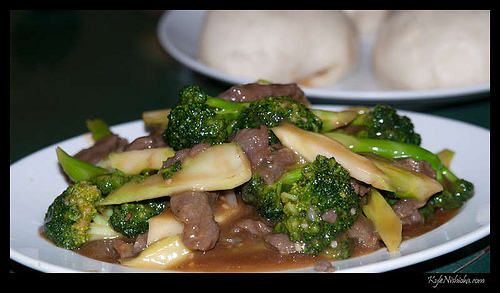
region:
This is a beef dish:
[106, 137, 238, 233]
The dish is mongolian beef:
[147, 104, 347, 260]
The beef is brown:
[130, 190, 270, 256]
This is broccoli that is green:
[230, 120, 387, 290]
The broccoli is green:
[250, 130, 338, 281]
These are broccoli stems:
[92, 160, 194, 187]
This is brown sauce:
[70, 210, 333, 282]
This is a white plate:
[50, 255, 85, 283]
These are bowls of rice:
[230, 16, 381, 97]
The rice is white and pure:
[199, 40, 358, 91]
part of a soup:
[225, 220, 256, 275]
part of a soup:
[253, 218, 280, 247]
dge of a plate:
[427, 209, 453, 256]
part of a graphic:
[445, 264, 482, 286]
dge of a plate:
[418, 238, 442, 264]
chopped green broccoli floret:
[164, 87, 244, 146]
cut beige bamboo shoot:
[90, 139, 252, 205]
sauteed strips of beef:
[170, 189, 222, 253]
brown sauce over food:
[78, 229, 473, 274]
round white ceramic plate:
[6, 103, 493, 273]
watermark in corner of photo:
[422, 269, 488, 290]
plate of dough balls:
[152, 10, 489, 107]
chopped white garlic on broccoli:
[290, 233, 339, 255]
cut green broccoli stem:
[52, 135, 115, 184]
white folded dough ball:
[198, 13, 360, 92]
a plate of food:
[3, 77, 488, 257]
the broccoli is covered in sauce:
[158, 56, 402, 225]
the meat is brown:
[182, 60, 317, 190]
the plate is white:
[0, 79, 472, 260]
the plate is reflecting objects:
[412, 189, 488, 254]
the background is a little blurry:
[37, 0, 480, 110]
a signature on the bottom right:
[419, 269, 497, 289]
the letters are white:
[419, 266, 495, 287]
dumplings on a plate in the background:
[156, 3, 468, 85]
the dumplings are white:
[176, 0, 478, 113]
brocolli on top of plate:
[180, 88, 245, 151]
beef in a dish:
[170, 185, 226, 252]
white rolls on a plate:
[211, 13, 491, 87]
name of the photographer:
[416, 255, 491, 290]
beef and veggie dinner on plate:
[31, 81, 481, 264]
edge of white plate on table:
[7, 128, 57, 201]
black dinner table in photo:
[21, 21, 133, 88]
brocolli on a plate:
[272, 168, 357, 248]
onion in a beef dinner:
[107, 147, 297, 206]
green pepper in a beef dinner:
[51, 148, 123, 186]